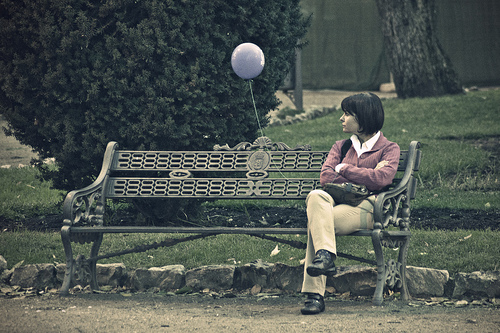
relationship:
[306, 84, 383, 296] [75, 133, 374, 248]
girl on bench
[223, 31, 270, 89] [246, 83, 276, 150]
balloon has string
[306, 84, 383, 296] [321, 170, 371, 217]
girl has bag